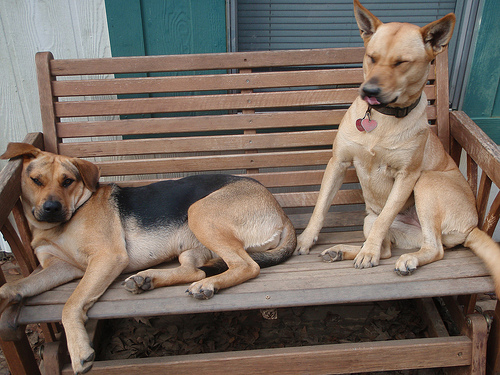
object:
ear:
[2, 143, 40, 163]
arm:
[32, 213, 79, 270]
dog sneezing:
[327, 24, 478, 272]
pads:
[120, 274, 154, 295]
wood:
[1, 0, 127, 185]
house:
[0, 0, 497, 255]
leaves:
[128, 322, 343, 348]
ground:
[448, 125, 473, 168]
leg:
[352, 167, 419, 269]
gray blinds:
[233, 1, 461, 51]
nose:
[360, 82, 384, 96]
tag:
[356, 117, 377, 133]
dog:
[0, 141, 298, 375]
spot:
[110, 165, 220, 240]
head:
[0, 142, 98, 231]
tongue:
[363, 95, 381, 105]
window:
[232, 0, 474, 108]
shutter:
[103, 0, 229, 140]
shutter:
[460, 0, 499, 146]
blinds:
[255, 15, 347, 44]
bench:
[0, 42, 500, 375]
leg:
[317, 212, 393, 266]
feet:
[133, 279, 150, 289]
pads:
[185, 281, 219, 301]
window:
[229, 1, 496, 151]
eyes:
[359, 51, 413, 69]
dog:
[292, 0, 497, 299]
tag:
[361, 119, 377, 133]